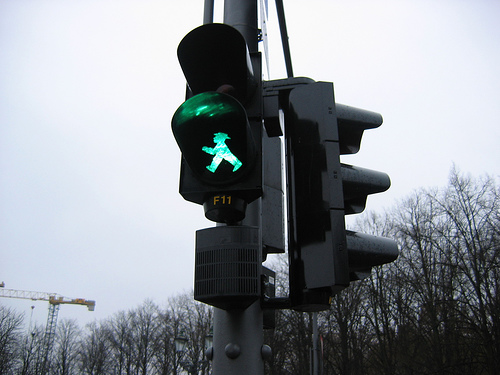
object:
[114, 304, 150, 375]
tree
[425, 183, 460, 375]
tree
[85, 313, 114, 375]
tree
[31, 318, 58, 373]
tree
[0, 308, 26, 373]
tree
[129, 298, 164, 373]
tree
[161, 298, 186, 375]
tree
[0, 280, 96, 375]
crane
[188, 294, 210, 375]
tree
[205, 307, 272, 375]
pole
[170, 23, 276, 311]
traffic light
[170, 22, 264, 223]
walking sign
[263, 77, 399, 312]
stoplight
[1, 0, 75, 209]
sky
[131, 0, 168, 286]
sky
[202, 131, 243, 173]
man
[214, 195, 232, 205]
f11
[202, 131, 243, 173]
symbol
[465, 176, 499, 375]
tree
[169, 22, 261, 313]
light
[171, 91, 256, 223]
sign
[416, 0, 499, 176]
sky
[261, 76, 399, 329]
box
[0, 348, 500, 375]
road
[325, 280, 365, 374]
tree